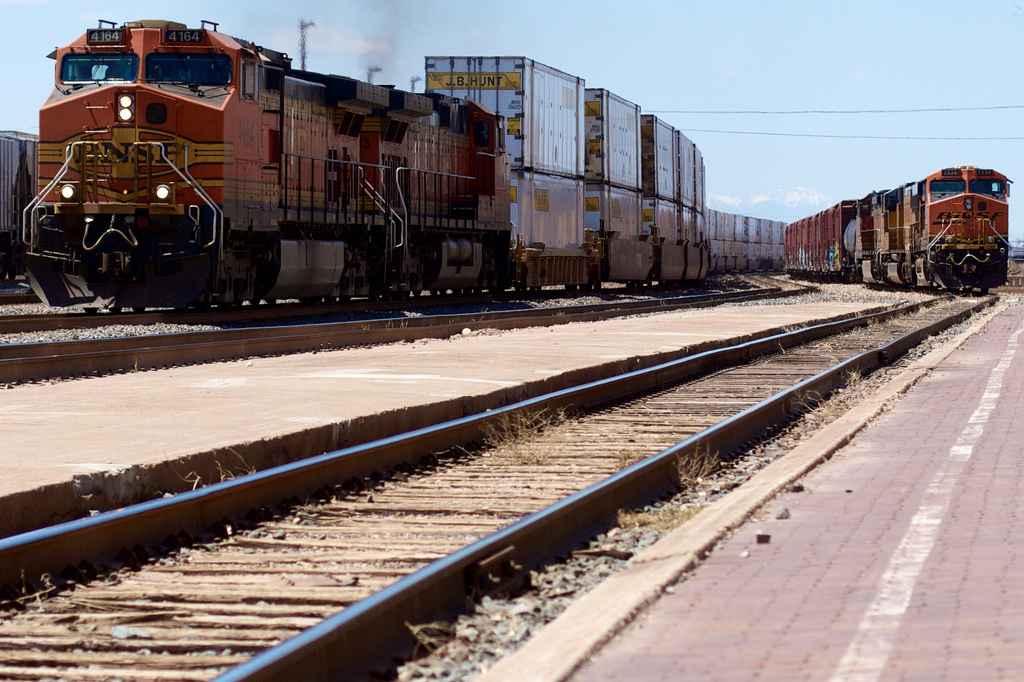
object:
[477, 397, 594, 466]
plant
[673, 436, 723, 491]
plant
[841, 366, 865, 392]
plant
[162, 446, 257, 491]
plant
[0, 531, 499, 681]
woods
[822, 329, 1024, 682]
dash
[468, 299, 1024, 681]
pathway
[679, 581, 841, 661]
bricks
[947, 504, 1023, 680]
bricks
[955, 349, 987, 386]
bricks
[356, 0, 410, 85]
smoke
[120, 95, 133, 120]
lights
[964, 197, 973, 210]
lights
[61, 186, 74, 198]
lights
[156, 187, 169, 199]
lights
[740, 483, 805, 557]
stones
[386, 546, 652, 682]
stones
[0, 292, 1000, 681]
railing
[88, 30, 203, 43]
numbers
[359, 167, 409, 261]
handle bars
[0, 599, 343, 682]
wood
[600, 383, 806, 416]
wood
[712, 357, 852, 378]
wood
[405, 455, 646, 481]
wood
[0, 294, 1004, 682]
track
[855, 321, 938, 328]
wood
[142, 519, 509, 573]
wood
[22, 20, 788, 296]
cars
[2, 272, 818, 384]
tracks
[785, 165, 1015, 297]
long train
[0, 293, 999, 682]
train tracks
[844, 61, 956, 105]
white clouds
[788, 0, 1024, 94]
white skys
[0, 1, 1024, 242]
blue sky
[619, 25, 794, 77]
clouds